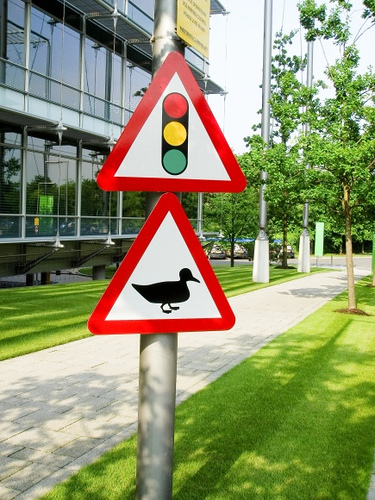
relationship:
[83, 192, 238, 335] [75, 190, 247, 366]
duck sign on sign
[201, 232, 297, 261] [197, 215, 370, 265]
cars parked in lot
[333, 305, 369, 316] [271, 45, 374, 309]
mulch under tree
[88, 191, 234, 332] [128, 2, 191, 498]
sign on pole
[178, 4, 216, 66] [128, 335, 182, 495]
sign on pole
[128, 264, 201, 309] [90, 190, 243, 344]
duck shadow on sign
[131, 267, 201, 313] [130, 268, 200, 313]
silhouette of a black duck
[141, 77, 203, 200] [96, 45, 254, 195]
traffic light next to sign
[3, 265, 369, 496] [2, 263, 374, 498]
sidewalk cuts through lawn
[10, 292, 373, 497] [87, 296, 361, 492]
shadows cuts through grass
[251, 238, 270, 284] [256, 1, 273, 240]
cement base for light post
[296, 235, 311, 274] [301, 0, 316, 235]
cement base for light post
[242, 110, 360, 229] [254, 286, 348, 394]
tree by sidewalk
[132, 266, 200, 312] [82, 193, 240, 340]
black duck on sign